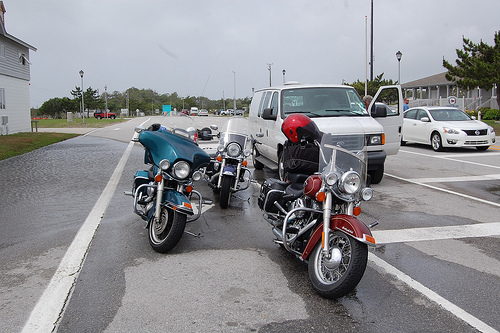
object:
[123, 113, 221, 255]
motorcycle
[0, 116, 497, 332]
street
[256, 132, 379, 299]
motorcycle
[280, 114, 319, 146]
helmet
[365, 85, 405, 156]
door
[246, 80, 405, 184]
van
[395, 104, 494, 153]
car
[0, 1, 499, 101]
sky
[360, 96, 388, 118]
man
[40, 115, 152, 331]
line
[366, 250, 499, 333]
line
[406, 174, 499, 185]
line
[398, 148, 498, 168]
line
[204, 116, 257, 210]
motorcycle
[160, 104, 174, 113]
sign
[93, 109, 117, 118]
truck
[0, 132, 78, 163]
grass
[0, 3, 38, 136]
buildig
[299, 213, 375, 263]
fender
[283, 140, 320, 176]
sleepig bag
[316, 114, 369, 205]
wnidshield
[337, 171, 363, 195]
headlight